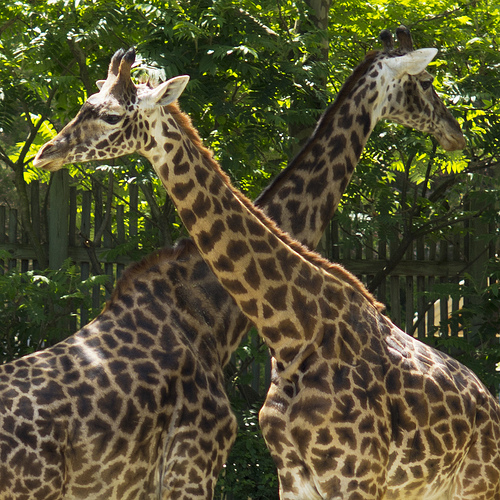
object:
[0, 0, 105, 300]
tree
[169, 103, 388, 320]
fur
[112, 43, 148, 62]
black hairs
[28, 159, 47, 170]
lip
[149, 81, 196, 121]
ear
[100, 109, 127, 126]
giraffe's eye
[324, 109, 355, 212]
neck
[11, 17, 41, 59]
leaves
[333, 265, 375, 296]
hairs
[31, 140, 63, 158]
nose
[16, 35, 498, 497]
giraffe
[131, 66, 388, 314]
brown mane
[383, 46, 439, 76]
ear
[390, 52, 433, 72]
back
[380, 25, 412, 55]
protrusions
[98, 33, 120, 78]
horn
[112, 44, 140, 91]
horn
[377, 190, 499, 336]
fence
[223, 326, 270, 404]
fence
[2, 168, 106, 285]
fence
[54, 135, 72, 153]
nostril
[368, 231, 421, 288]
branch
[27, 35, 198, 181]
head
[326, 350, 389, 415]
lines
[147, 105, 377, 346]
neck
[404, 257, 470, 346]
object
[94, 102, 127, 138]
eye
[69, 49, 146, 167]
photo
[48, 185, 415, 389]
number